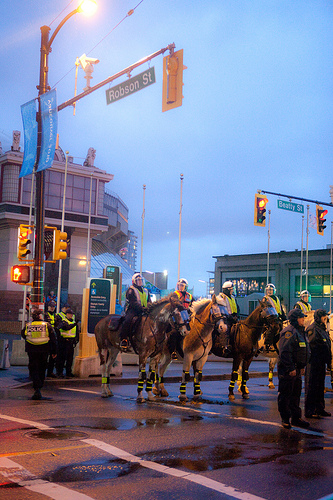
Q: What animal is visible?
A: Horses.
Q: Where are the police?
A: On horses.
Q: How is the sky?
A: Clear.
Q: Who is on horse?
A: Officer.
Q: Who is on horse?
A: Police officer.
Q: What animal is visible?
A: Horse.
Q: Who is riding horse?
A: Officer.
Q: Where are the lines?
A: Cross walk.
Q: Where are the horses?
A: On street.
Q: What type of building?
A: Multi story.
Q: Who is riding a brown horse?
A: A cop.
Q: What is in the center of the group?
A: A dark horse with a rider.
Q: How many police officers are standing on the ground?
A: Six.